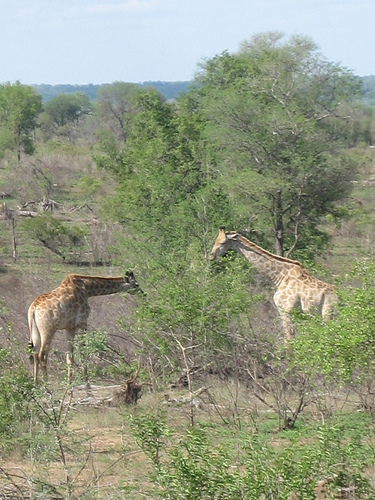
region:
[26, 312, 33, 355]
tail on the giraffe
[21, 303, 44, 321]
rear end of giraffe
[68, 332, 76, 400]
one of the giraffe's legs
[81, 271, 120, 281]
hair on giraffe's neck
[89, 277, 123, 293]
part of the giraffe's neck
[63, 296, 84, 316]
spots on the giraffe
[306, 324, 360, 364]
green foliage near giraffe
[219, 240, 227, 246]
an eye on giraffe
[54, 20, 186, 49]
part of the sky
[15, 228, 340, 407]
2 giraffes on ground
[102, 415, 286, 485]
the ground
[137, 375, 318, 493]
the ground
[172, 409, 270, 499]
the ground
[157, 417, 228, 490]
the ground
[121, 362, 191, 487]
the ground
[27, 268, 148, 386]
giraffe eating from tree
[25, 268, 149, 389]
brown and white spotted giraffe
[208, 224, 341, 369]
brown and white spotted giraffe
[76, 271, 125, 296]
giraffe with long neck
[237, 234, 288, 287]
giraffe with long neck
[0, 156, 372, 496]
grass dry and brown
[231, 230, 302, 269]
brown mane on giraffe's neck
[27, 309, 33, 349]
tail of giraffe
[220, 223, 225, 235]
horn on head of giraffe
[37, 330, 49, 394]
hind leg of giraffe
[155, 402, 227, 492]
The trees are visible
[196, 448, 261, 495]
The trees are visible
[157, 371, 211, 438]
The trees are visible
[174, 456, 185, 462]
The trees are visible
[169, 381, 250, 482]
The trees are visible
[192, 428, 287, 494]
The trees are visible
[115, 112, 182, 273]
The trees are visible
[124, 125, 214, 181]
The trees are visible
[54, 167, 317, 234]
The trees are visible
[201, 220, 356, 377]
giraffe eating green leaves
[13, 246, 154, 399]
giraffe bending neck to eat leaves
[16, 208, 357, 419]
giraffes dining on leaves together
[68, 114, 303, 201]
tall trees for giraffes to eat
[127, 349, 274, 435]
dead branches by the ground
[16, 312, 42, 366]
swinging tail of a giraffe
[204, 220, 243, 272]
head of a giraffe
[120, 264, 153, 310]
head of a giraffe in the leaves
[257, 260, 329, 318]
sun faded pattern on a giraffe's back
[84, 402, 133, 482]
grass on the savannah